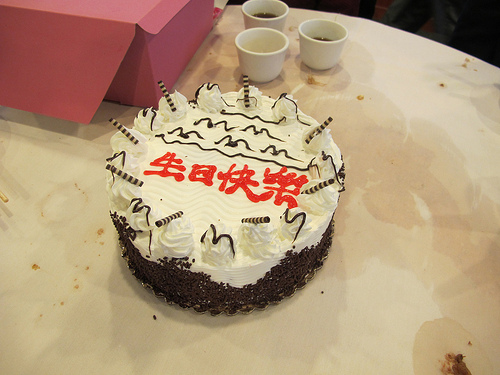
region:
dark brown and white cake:
[103, 68, 348, 320]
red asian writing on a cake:
[139, 148, 306, 213]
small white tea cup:
[229, 23, 295, 83]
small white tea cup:
[237, 0, 292, 35]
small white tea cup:
[297, 15, 346, 72]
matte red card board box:
[0, 0, 226, 130]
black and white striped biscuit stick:
[231, 70, 252, 109]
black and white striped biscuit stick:
[299, 113, 338, 148]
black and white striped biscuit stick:
[100, 157, 152, 191]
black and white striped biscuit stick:
[150, 77, 181, 116]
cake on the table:
[66, 72, 386, 327]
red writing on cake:
[146, 144, 314, 222]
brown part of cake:
[246, 240, 323, 297]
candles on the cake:
[83, 99, 358, 270]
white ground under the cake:
[353, 215, 453, 304]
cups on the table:
[203, 8, 349, 90]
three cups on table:
[214, 3, 374, 79]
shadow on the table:
[317, 253, 431, 358]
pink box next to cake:
[20, 8, 163, 128]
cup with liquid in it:
[296, 28, 350, 78]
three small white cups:
[231, 4, 341, 73]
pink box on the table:
[4, 2, 234, 107]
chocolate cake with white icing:
[102, 74, 349, 308]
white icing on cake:
[98, 71, 347, 276]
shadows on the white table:
[239, 32, 498, 334]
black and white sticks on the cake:
[101, 66, 353, 246]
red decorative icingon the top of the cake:
[142, 143, 305, 214]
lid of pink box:
[1, 1, 190, 125]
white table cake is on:
[2, 2, 492, 373]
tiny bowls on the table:
[232, 4, 342, 75]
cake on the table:
[1, 19, 201, 125]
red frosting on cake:
[135, 145, 310, 221]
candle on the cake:
[150, 190, 195, 241]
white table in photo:
[335, 215, 435, 315]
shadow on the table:
[335, 200, 450, 310]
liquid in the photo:
[285, 10, 370, 80]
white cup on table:
[290, 10, 355, 70]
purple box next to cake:
[48, 3, 200, 109]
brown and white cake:
[107, 89, 334, 301]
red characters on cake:
[119, 136, 314, 264]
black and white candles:
[222, 55, 363, 195]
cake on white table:
[97, 145, 348, 325]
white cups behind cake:
[224, 1, 357, 101]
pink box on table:
[0, 6, 232, 116]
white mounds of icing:
[104, 104, 302, 268]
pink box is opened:
[0, 2, 221, 129]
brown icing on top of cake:
[130, 86, 310, 163]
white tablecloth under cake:
[76, 102, 361, 308]